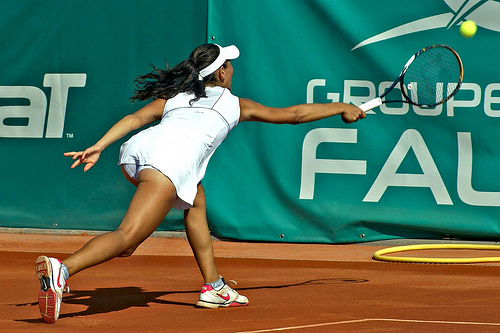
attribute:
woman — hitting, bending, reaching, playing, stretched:
[35, 36, 367, 322]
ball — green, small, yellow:
[460, 19, 477, 39]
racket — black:
[360, 44, 465, 113]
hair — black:
[129, 41, 228, 106]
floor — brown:
[2, 231, 499, 331]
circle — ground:
[372, 243, 499, 265]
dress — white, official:
[118, 84, 242, 212]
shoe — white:
[196, 281, 249, 309]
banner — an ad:
[2, 2, 499, 243]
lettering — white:
[2, 72, 499, 207]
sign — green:
[2, 5, 497, 229]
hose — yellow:
[372, 242, 498, 264]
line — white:
[247, 317, 499, 332]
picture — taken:
[1, 3, 496, 332]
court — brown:
[5, 228, 497, 332]